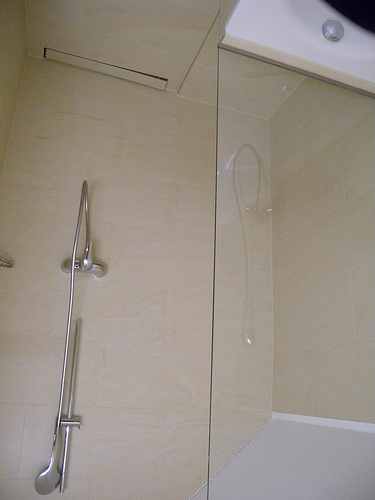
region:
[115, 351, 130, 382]
this is the wall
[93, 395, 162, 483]
the wall is made of tiles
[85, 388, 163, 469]
the tiles are cream in color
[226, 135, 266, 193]
this is a door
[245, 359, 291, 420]
the door is made of glass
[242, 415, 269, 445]
the glass is clear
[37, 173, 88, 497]
this is a pipe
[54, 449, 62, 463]
the pipe is shiny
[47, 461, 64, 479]
the pipe is metallic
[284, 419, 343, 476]
the floor is white in color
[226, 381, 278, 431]
part of a glass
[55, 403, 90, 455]
part of a metal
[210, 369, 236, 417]
part of a glass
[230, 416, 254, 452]
par tof a line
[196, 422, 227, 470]
part of a mirror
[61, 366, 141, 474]
part of a glass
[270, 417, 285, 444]
part of a floor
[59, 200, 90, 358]
the hose is silver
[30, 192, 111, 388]
the hose is silver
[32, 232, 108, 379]
the hose is made of metal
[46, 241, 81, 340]
the hose is made of metal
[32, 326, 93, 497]
the shower head is silver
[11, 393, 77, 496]
the shower head is silver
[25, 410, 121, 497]
the shower head is silver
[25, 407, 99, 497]
shower head is made of metal